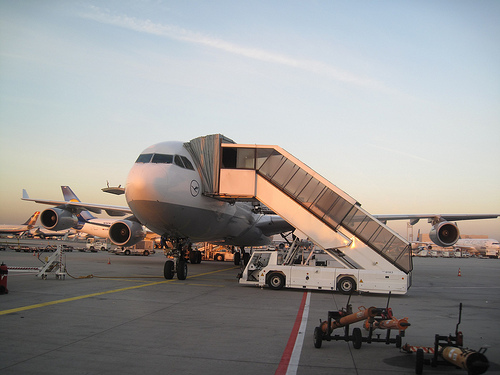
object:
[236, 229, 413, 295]
vehicle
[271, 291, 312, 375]
stripe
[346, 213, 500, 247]
wing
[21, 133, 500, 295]
plane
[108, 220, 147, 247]
engine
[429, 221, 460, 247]
engine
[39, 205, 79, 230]
engine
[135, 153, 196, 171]
window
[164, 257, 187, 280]
wheels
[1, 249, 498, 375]
runway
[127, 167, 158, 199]
nose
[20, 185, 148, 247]
wing